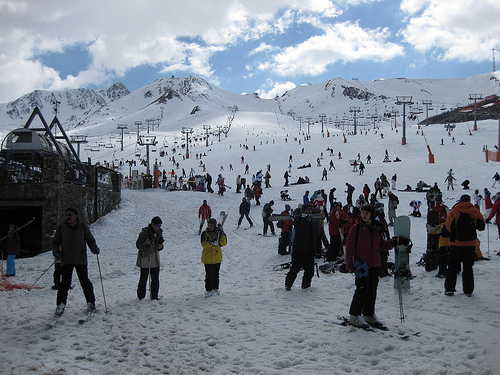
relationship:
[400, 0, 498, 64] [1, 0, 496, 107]
cloud in sky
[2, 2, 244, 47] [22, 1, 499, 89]
cloud in sky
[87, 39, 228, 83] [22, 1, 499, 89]
cloud in sky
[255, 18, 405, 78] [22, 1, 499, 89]
cloud in sky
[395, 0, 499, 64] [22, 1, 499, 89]
cloud in sky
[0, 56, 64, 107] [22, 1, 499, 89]
cloud in sky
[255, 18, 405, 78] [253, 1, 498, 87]
cloud in sky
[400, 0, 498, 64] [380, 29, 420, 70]
cloud in sky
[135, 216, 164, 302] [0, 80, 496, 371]
person in snow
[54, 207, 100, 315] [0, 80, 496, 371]
person in snow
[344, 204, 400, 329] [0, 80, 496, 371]
person on snow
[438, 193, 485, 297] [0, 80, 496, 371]
person on snow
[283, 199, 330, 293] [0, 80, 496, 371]
skier on snow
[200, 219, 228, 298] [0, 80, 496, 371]
person on snow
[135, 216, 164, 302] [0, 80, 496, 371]
person on snow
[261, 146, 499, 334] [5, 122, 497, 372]
peope on field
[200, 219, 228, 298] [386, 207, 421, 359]
person hold skis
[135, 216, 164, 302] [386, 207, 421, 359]
person hold skis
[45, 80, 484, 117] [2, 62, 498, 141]
snow cover mountains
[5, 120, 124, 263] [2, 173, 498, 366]
train on field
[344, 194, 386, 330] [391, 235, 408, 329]
person hold snow poles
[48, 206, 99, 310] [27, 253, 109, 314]
person hold ski poles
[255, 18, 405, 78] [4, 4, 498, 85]
cloud in sky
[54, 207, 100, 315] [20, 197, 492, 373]
person on snow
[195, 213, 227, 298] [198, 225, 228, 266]
person wearing yellow jacket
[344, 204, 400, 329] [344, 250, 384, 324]
person wearing pants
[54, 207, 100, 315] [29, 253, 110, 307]
person holding ski poles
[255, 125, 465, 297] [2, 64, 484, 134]
peope on mountain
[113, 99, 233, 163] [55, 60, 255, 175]
poles on mountain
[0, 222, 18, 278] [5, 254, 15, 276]
person wears pants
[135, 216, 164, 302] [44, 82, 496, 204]
person on hill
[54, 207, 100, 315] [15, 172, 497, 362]
person on hill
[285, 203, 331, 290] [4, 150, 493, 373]
skier on hill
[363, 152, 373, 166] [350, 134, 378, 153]
skier on a hill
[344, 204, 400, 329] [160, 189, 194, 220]
person on a hill